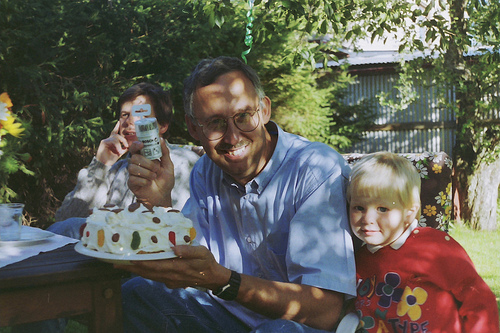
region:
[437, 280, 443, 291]
part of a sweater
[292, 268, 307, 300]
part of an arm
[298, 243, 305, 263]
part of a shirt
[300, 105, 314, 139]
part of a forest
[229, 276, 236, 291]
part of a watch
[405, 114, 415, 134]
part of a board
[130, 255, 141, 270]
part of a plate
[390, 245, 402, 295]
part of a sweater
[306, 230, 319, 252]
part of a shirt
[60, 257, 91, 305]
part of a table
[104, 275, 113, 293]
edge of a table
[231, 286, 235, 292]
part of a clock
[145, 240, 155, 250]
part of a cake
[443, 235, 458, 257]
part of a sweater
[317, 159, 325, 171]
part of an elbow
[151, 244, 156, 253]
edge of a plate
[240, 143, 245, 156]
part of a mouth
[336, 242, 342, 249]
part of a shirt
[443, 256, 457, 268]
part of a sweater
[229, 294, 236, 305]
part of a watch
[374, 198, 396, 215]
eye of a baby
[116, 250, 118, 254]
part of a plate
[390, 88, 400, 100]
part of a steel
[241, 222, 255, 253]
part of a button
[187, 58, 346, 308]
man wearing glasses and a blue shirt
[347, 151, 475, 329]
blond child wearing a red shirt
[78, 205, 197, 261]
cake with white frosting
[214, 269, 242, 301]
black watch on the man's wrist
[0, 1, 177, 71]
green leaves on the trees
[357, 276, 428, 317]
flowers on a red shirt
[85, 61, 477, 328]
three people sitting outside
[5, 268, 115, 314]
brown wooden table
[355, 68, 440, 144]
corrugated metal building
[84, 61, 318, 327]
man holding a cake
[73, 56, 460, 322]
an older man, woman and small boy with a birthday cake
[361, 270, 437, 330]
flowers on the red shirt the boy is wearing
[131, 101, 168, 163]
white container the man is holding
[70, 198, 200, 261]
white frosted cake decorated with colorful gummis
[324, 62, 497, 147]
steel storage shed in the background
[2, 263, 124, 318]
end of a dark wooden table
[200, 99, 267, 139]
wire-rimmed eyeglasses the man is wearing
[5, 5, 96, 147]
green leafy bushes in the background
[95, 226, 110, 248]
large yellow gummi on the white cake